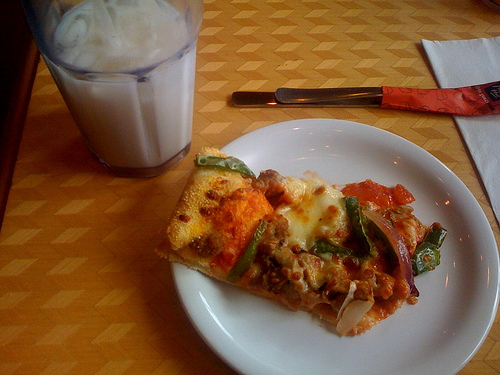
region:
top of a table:
[73, 263, 98, 310]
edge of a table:
[1, 176, 21, 216]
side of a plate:
[228, 305, 239, 325]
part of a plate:
[260, 328, 285, 351]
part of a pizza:
[308, 278, 331, 334]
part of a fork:
[337, 88, 354, 105]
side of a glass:
[113, 120, 118, 123]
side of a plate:
[313, 119, 330, 136]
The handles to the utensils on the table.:
[234, 75, 375, 118]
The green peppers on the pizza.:
[203, 133, 444, 320]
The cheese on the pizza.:
[224, 161, 358, 251]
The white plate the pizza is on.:
[172, 133, 497, 362]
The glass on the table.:
[46, 1, 201, 170]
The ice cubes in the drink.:
[57, 13, 171, 67]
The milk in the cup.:
[59, 14, 197, 156]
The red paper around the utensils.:
[384, 65, 499, 135]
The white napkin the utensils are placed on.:
[429, 28, 498, 168]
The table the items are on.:
[39, 12, 476, 374]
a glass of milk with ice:
[38, 0, 195, 177]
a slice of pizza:
[157, 148, 442, 341]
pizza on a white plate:
[157, 119, 497, 373]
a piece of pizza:
[165, 118, 498, 374]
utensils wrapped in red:
[223, 80, 498, 117]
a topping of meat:
[244, 245, 403, 303]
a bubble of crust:
[202, 185, 264, 268]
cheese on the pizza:
[247, 185, 339, 269]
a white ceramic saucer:
[172, 118, 496, 372]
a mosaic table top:
[4, 182, 161, 372]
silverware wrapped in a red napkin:
[227, 72, 498, 114]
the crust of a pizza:
[170, 172, 202, 254]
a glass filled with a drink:
[48, 27, 199, 172]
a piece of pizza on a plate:
[179, 147, 434, 327]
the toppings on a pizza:
[266, 193, 403, 300]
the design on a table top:
[34, 210, 130, 341]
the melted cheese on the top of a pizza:
[293, 192, 342, 232]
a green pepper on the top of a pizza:
[196, 146, 253, 180]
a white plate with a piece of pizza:
[200, 126, 491, 372]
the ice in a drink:
[81, 20, 162, 62]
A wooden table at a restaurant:
[14, 170, 154, 365]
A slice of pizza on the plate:
[168, 154, 420, 326]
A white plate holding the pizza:
[178, 128, 487, 366]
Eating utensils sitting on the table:
[198, 71, 499, 126]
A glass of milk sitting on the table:
[11, 3, 211, 180]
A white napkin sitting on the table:
[389, 20, 499, 232]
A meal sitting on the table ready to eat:
[4, 9, 496, 366]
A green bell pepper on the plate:
[416, 214, 455, 286]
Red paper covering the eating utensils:
[379, 80, 498, 132]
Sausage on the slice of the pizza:
[259, 238, 345, 311]